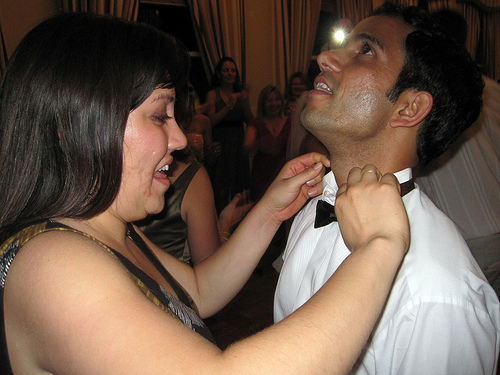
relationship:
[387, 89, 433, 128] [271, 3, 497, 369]
ear of person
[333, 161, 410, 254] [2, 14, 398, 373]
hand of person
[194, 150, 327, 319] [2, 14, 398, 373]
hand of person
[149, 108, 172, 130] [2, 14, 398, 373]
eye of person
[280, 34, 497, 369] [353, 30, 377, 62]
person with eye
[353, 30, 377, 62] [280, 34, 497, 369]
eye on person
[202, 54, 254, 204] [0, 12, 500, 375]
person standing in a room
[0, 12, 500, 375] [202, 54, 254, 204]
room with person standing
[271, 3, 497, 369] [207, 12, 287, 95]
person in a room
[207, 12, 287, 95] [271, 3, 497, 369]
room with a person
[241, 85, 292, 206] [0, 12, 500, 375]
partyers in a room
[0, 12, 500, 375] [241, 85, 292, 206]
room with a partyers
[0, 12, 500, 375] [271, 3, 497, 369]
room with a person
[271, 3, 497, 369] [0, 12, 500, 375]
person in a room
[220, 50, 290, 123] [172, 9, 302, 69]
people in background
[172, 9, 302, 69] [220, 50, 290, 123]
background with people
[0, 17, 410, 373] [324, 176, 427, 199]
woman with collar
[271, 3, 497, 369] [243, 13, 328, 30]
person looking into air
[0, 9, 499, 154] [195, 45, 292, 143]
background with partyers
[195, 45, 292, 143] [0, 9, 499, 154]
partyers with background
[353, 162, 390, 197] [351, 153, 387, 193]
ring with finger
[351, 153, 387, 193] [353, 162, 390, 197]
finger with ring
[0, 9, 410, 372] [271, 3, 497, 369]
woman touching person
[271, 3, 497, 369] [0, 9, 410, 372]
person in front of woman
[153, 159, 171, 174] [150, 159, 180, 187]
teeth in mouth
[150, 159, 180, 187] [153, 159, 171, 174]
mouth with teeth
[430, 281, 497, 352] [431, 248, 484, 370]
wrinkles on shirt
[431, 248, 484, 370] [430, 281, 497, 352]
shirt full of wrinkles